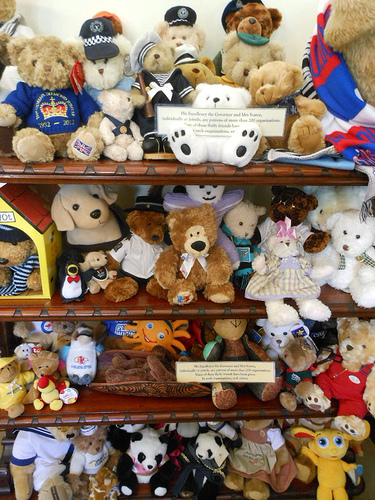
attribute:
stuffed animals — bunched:
[3, 4, 371, 166]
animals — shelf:
[50, 21, 259, 150]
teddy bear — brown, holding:
[164, 194, 287, 312]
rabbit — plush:
[257, 221, 323, 324]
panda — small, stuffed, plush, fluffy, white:
[104, 435, 198, 491]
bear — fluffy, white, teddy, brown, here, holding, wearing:
[306, 213, 373, 272]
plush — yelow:
[273, 420, 338, 500]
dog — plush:
[62, 183, 127, 238]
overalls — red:
[331, 358, 370, 412]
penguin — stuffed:
[58, 243, 125, 326]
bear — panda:
[166, 402, 258, 483]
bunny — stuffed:
[294, 425, 360, 495]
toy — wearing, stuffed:
[4, 54, 103, 167]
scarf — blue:
[299, 37, 373, 95]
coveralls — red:
[308, 348, 373, 428]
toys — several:
[97, 59, 299, 385]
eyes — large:
[309, 433, 339, 447]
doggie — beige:
[43, 184, 153, 286]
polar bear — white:
[177, 46, 323, 211]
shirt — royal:
[31, 99, 78, 125]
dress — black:
[134, 75, 207, 127]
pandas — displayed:
[109, 393, 299, 496]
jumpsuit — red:
[302, 355, 369, 403]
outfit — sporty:
[24, 64, 119, 177]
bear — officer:
[145, 1, 214, 73]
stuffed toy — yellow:
[258, 425, 352, 494]